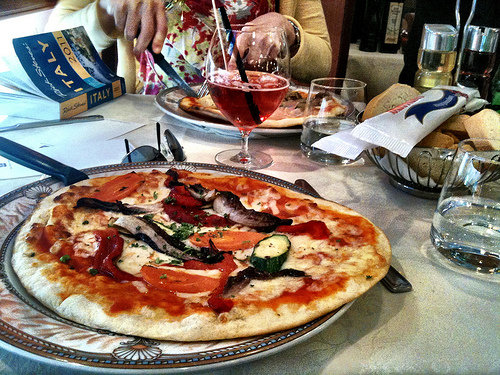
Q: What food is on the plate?
A: Pizza.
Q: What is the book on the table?
A: Italy guidebook.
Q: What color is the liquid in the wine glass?
A: Red.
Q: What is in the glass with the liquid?
A: Black straw.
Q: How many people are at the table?
A: 1.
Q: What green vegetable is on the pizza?
A: ZUCCHINI.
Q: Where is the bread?
A: Wire basket.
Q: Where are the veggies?
A: On the pizza.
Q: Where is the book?
A: On the table.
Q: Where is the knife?
A: In the hand.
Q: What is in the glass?
A: Wine.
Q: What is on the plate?
A: Pizza.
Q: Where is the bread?
A: Basket.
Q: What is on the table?
A: Salad dressing.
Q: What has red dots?
A: Blouse.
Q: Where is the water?
A: In the glass.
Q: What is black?
A: Straw.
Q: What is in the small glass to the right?
A: Water.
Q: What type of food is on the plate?
A: Pizza.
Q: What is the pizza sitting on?
A: A plate.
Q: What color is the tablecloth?
A: White.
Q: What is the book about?
A: Italy.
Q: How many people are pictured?
A: One.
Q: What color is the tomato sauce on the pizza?
A: Red.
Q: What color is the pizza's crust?
A: White.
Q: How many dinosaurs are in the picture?
A: Zero.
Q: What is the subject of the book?
A: A guide of Italy 2011.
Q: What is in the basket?
A: Bread.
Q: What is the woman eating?
A: Pizza.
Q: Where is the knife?
A: Under the plate.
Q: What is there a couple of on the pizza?
A: Tomatoes.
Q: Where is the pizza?
A: On a tray.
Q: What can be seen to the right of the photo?
A: A glass of water.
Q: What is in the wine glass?
A: A drink.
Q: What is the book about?
A: Italy.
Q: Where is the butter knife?
A: On the table.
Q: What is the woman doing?
A: Cutting a pizza.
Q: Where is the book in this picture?
A: On the table.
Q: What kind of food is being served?
A: Pizza.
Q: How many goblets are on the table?
A: One.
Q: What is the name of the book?
A: Italy.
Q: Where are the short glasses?
A: On the table.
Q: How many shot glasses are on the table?
A: Two.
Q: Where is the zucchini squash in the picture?
A: On the pizza.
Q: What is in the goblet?
A: Wine.